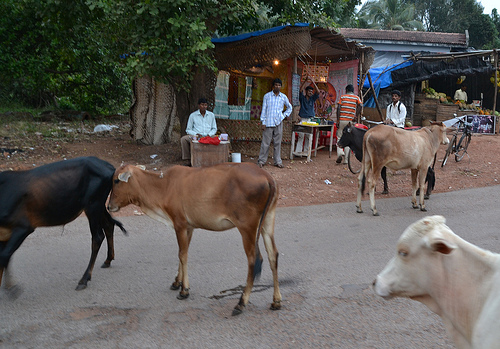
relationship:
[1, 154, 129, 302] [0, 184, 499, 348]
cow standing on road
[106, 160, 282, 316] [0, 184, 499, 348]
cow standing on road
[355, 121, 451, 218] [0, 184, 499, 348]
cow standing on road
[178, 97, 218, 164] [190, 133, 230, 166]
man sitting behind desk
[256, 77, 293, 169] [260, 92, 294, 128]
man wearing shirt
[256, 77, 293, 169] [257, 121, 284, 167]
man wearing pants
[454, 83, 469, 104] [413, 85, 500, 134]
man standing behind stand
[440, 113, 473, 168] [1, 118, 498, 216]
bicycle standing on ground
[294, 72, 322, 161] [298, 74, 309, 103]
person has arm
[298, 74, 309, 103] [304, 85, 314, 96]
arm over head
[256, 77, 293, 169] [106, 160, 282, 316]
man watching cow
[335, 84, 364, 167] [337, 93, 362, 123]
man wearing shirt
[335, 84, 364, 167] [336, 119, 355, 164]
man wearing pants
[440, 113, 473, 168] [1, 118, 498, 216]
bicycle parked on ground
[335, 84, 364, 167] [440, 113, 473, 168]
man has bicycle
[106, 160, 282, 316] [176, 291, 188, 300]
cow has hoof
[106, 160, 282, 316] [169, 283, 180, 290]
cow has hoof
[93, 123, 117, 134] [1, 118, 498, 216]
garbage lying on ground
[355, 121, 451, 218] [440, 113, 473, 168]
cow standing near bicycle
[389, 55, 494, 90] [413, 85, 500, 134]
tarp covering stand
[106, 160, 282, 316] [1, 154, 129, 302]
cow bumps cow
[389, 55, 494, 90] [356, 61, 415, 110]
tarp besides tarp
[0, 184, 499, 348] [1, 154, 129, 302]
road trod by cow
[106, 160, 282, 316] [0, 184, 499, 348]
cow standing in road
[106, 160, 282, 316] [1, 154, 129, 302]
cow pushing cow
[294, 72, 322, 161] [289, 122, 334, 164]
person behind table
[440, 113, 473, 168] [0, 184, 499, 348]
bicycle on side of road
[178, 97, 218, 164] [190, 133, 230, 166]
man in front of desk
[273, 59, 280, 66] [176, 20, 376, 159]
light hanging in store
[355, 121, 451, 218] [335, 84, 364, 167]
cow standing near man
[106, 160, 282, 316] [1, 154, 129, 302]
cow touching cow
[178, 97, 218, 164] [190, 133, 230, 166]
man seated at desk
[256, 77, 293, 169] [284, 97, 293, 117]
man has arm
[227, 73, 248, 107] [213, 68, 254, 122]
window surrounded by material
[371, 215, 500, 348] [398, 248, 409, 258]
cow has eye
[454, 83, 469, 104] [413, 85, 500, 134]
man standing at stand